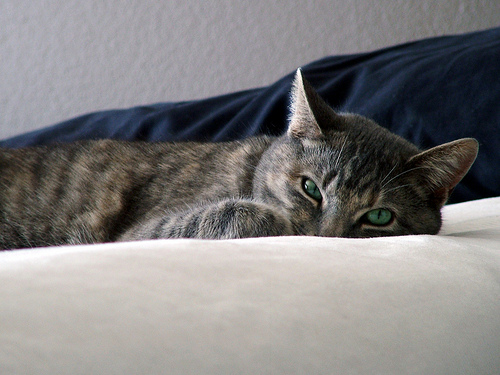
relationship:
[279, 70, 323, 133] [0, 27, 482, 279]
ear of cat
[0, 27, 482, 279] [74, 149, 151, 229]
cat has astripes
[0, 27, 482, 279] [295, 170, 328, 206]
cat has eye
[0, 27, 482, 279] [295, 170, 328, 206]
kitty has eye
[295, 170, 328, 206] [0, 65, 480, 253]
eye on cat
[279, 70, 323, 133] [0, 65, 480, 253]
ear of cat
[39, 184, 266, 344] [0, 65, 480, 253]
leg of cat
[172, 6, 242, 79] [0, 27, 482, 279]
wall behind bed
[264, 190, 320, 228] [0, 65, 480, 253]
whisker on cat